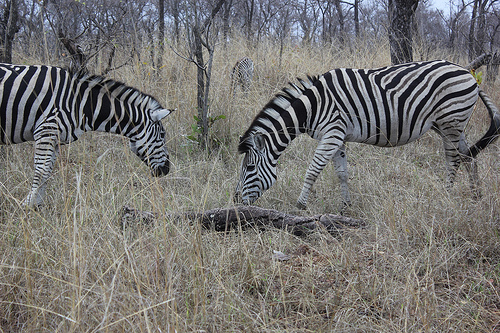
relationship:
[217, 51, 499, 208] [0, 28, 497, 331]
zebra in grass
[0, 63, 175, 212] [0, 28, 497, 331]
zebra in grass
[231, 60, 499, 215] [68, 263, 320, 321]
zebra in grass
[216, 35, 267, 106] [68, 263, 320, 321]
zebra in grass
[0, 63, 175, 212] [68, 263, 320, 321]
zebra in grass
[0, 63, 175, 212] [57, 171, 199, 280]
zebra in grass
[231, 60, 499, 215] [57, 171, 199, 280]
zebra in grass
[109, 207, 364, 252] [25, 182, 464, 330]
log on grass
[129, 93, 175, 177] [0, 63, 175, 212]
head of a zebra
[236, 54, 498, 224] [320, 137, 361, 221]
zebra has leg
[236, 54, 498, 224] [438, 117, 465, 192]
zebra has leg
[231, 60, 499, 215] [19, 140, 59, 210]
zebra has leg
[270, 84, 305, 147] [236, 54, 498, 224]
neck of zebra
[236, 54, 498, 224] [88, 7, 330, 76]
zebra in wild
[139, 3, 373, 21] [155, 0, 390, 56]
sky through trees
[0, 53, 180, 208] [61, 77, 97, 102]
animal has fur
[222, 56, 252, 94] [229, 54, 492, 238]
tail of zebra